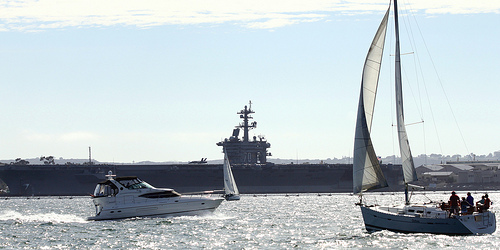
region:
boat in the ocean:
[69, 162, 224, 218]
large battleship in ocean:
[7, 137, 427, 186]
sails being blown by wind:
[349, 17, 398, 192]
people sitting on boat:
[443, 192, 496, 224]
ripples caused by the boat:
[11, 207, 76, 227]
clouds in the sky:
[8, 0, 355, 32]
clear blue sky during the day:
[7, 30, 345, 97]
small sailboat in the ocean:
[214, 150, 248, 205]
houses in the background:
[428, 159, 499, 185]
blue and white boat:
[351, 200, 481, 242]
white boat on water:
[61, 183, 223, 219]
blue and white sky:
[84, 9, 261, 108]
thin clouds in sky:
[85, 7, 292, 47]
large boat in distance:
[0, 118, 395, 195]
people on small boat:
[434, 181, 494, 223]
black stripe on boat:
[87, 200, 207, 226]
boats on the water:
[50, 38, 494, 236]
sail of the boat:
[327, 1, 426, 186]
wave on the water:
[0, 205, 80, 226]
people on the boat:
[446, 187, 492, 232]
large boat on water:
[0, 154, 337, 193]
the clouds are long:
[97, 5, 344, 42]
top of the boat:
[226, 95, 262, 168]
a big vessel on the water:
[14, 111, 406, 203]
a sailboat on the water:
[362, 18, 490, 243]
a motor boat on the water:
[81, 162, 231, 237]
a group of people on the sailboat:
[451, 177, 492, 221]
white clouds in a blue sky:
[13, 6, 477, 75]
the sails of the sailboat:
[368, 30, 425, 200]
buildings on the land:
[417, 148, 498, 188]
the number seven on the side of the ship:
[7, 160, 39, 200]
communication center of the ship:
[231, 102, 282, 184]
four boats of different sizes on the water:
[19, 30, 476, 247]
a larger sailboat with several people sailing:
[352, 1, 499, 237]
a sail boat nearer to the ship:
[221, 151, 241, 201]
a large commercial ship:
[6, 96, 410, 194]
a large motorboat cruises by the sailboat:
[91, 174, 225, 220]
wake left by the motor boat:
[6, 204, 91, 234]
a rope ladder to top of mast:
[387, 16, 429, 193]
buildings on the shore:
[414, 160, 499, 196]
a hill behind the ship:
[10, 155, 104, 165]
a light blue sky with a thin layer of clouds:
[6, 24, 493, 149]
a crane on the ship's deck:
[85, 144, 96, 161]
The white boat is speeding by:
[91, 176, 229, 221]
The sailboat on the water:
[352, 1, 497, 236]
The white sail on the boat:
[353, 4, 392, 196]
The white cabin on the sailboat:
[401, 204, 443, 217]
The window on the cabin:
[406, 207, 416, 212]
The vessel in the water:
[2, 101, 404, 193]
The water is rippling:
[1, 191, 499, 248]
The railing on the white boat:
[126, 188, 224, 208]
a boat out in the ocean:
[87, 163, 225, 249]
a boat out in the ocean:
[348, 174, 498, 249]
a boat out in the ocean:
[210, 145, 257, 214]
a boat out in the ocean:
[3, 134, 418, 196]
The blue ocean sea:
[32, 211, 327, 246]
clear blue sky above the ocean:
[35, 28, 395, 87]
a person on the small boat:
[442, 186, 462, 211]